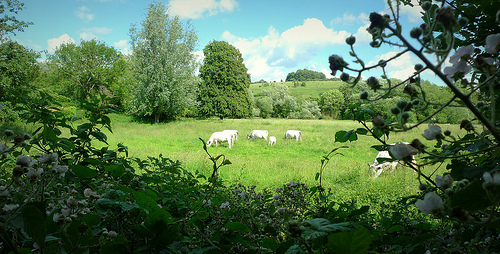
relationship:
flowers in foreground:
[13, 132, 94, 225] [5, 144, 492, 253]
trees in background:
[54, 24, 260, 121] [7, 9, 488, 116]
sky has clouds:
[3, 0, 492, 81] [227, 17, 338, 74]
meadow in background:
[249, 82, 341, 96] [7, 9, 488, 116]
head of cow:
[203, 138, 214, 148] [200, 129, 235, 151]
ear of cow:
[376, 165, 385, 171] [366, 142, 420, 179]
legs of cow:
[225, 137, 235, 150] [200, 129, 235, 151]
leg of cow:
[215, 138, 222, 152] [200, 129, 235, 151]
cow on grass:
[200, 129, 235, 151] [56, 116, 469, 203]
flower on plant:
[386, 133, 423, 167] [354, 3, 500, 253]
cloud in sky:
[166, 1, 232, 22] [3, 0, 492, 81]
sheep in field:
[206, 127, 308, 156] [56, 116, 469, 203]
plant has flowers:
[354, 3, 500, 253] [391, 30, 500, 158]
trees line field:
[54, 24, 260, 121] [56, 116, 469, 203]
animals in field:
[206, 127, 308, 156] [56, 116, 469, 203]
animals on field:
[206, 127, 308, 156] [56, 116, 469, 203]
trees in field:
[54, 24, 260, 121] [56, 116, 469, 203]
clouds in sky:
[227, 17, 338, 74] [3, 0, 492, 81]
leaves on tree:
[213, 96, 224, 102] [201, 41, 261, 121]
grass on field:
[136, 122, 207, 172] [56, 116, 469, 203]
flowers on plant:
[13, 132, 94, 225] [354, 3, 500, 253]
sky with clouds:
[3, 0, 492, 81] [227, 17, 338, 74]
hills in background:
[244, 81, 356, 101] [7, 9, 488, 116]